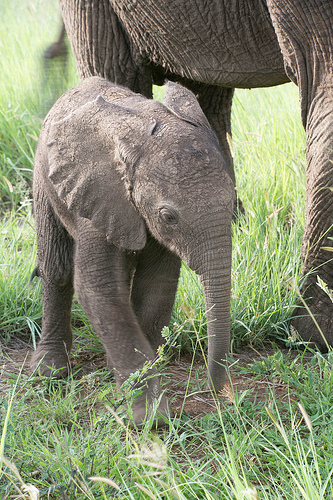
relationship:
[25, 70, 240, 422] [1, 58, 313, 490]
elephant standing in a field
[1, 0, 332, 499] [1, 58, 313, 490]
grass of field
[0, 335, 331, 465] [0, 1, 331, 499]
dirt of ground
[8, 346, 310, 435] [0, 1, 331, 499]
patch of ground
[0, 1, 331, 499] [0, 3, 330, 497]
ground in field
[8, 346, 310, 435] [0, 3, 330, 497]
patch in field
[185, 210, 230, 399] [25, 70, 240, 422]
trunk of elephant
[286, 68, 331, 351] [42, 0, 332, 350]
leg of an elephant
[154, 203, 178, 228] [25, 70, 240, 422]
eye of elephant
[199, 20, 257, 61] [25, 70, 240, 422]
skin of elephant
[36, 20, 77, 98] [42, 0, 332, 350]
tail of elephant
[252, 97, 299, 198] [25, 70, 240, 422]
grass growing behind elephant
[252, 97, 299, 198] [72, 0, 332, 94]
grass growing behind elephant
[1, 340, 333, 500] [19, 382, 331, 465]
grass growing on ground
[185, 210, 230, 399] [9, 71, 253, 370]
trunk of elephant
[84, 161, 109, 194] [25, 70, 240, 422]
skin of elephant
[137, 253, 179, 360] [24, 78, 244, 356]
leg of elephant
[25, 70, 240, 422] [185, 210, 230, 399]
elephant with trunk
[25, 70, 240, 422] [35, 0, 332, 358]
elephant near elephant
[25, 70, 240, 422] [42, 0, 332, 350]
elephant near elephant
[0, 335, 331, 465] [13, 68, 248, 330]
dirt under elephant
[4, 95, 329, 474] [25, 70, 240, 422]
grass between elephant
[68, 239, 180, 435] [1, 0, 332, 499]
foot in grass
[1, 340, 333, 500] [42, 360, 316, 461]
grass of grass